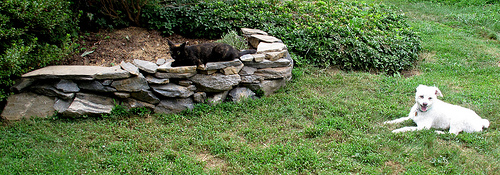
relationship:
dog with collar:
[388, 74, 493, 141] [410, 102, 427, 116]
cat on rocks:
[162, 33, 266, 72] [58, 58, 288, 121]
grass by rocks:
[98, 93, 221, 131] [58, 58, 288, 121]